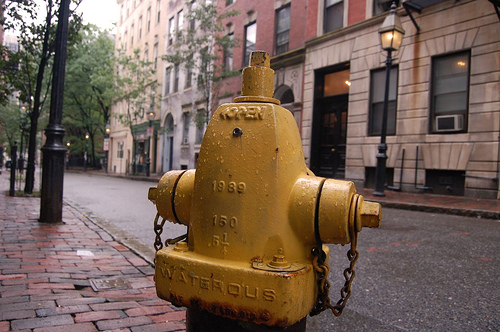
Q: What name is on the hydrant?
A: Waterous.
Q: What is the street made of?
A: Asphalt.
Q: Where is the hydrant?
A: Front middle.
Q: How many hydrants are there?
A: One.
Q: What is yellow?
A: Hydrant.